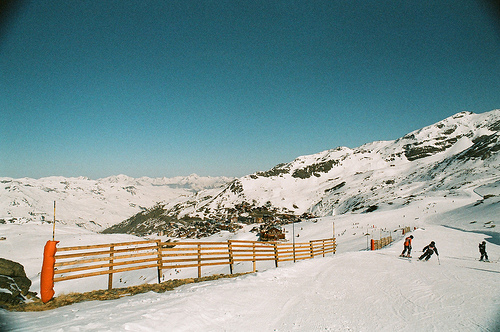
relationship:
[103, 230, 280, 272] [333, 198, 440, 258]
fence by skiing slope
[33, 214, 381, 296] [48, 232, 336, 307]
slats of fence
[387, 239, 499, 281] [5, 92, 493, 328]
trails on snow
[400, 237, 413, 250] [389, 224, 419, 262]
jacket on skier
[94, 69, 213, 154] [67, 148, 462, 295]
blue sky above land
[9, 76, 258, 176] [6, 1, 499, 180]
light in sky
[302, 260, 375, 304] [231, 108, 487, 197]
snow on mountains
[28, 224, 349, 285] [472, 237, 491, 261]
fence next to person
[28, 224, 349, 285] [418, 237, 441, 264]
fence next to person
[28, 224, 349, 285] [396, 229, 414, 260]
fence next to person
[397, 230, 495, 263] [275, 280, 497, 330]
people in snow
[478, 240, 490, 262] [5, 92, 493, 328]
person on snow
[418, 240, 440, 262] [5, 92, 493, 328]
person on snow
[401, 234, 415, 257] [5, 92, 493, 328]
people on snow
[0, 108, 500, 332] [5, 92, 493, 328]
hill covered in snow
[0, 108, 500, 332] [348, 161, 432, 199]
hill covered in snow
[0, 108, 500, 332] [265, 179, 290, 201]
hill covered in snow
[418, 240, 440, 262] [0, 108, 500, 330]
person going down hill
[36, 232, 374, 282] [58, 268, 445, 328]
fence running along snow